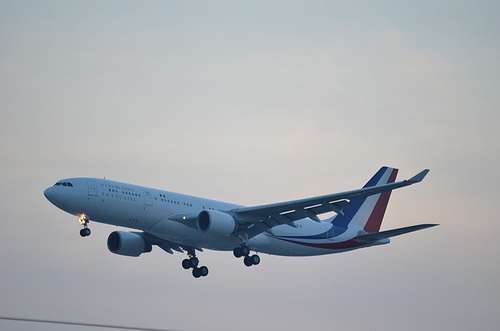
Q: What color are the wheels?
A: Black.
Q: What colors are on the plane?
A: Red and blue.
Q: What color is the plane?
A: White.